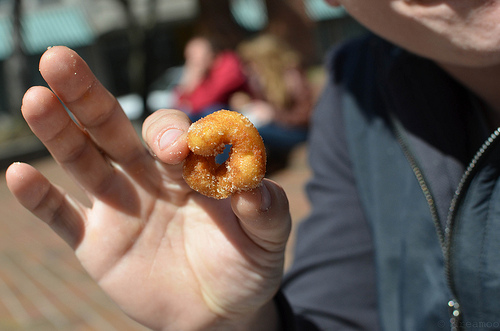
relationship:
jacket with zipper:
[275, 34, 499, 330] [377, 100, 485, 328]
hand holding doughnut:
[0, 42, 292, 327] [182, 108, 267, 198]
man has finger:
[5, 1, 499, 330] [140, 109, 190, 164]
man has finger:
[5, 1, 499, 330] [18, 85, 123, 202]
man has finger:
[5, 1, 499, 330] [8, 157, 81, 240]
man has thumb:
[5, 1, 499, 330] [225, 175, 297, 248]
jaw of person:
[411, 43, 499, 73] [283, 0, 489, 301]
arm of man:
[289, 101, 389, 328] [5, 1, 499, 330]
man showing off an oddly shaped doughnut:
[5, 1, 499, 328] [182, 108, 267, 198]